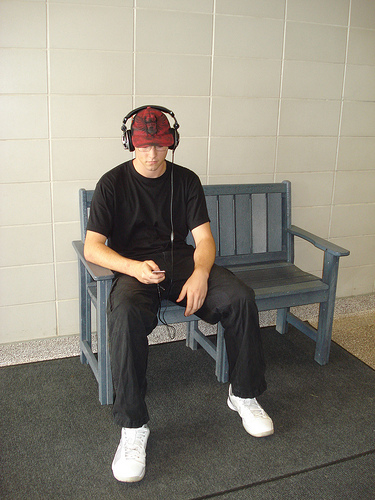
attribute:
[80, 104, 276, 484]
man — sitting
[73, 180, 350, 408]
bench — blue, wood, wooden, gray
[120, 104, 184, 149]
headphones — large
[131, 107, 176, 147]
hat — red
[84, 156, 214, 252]
shirt — black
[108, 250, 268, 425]
pants — black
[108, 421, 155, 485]
shoe — white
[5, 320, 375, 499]
rug — gray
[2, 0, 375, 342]
wall — white, tile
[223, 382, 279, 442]
shoe — white